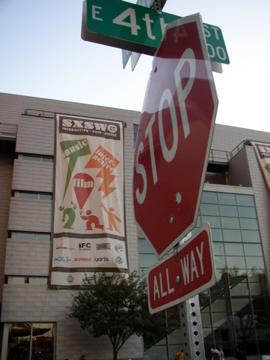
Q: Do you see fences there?
A: No, there are no fences.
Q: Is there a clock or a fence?
A: No, there are no fences or clocks.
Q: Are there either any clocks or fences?
A: No, there are no fences or clocks.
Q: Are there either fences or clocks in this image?
A: No, there are no fences or clocks.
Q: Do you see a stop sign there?
A: Yes, there is a stop sign.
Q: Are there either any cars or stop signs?
A: Yes, there is a stop sign.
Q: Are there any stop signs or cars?
A: Yes, there is a stop sign.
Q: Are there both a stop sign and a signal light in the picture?
A: No, there is a stop sign but no traffic lights.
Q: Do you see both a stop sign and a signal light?
A: No, there is a stop sign but no traffic lights.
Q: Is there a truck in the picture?
A: No, there are no trucks.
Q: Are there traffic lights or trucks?
A: No, there are no trucks or traffic lights.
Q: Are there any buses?
A: No, there are no buses.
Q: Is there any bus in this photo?
A: No, there are no buses.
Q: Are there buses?
A: No, there are no buses.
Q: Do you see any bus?
A: No, there are no buses.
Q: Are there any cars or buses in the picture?
A: No, there are no buses or cars.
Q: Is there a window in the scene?
A: Yes, there is a window.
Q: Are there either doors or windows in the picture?
A: Yes, there is a window.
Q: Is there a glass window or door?
A: Yes, there is a glass window.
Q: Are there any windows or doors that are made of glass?
A: Yes, the window is made of glass.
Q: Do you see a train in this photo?
A: No, there are no trains.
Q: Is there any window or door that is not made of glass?
A: No, there is a window but it is made of glass.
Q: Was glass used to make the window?
A: Yes, the window is made of glass.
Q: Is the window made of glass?
A: Yes, the window is made of glass.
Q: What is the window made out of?
A: The window is made of glass.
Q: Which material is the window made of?
A: The window is made of glass.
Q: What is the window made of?
A: The window is made of glass.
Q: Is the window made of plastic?
A: No, the window is made of glass.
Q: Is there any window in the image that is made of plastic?
A: No, there is a window but it is made of glass.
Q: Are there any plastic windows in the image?
A: No, there is a window but it is made of glass.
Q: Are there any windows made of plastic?
A: No, there is a window but it is made of glass.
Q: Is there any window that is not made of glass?
A: No, there is a window but it is made of glass.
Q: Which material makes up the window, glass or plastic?
A: The window is made of glass.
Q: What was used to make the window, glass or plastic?
A: The window is made of glass.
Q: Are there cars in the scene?
A: No, there are no cars.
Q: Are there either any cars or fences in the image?
A: No, there are no cars or fences.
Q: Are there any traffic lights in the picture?
A: No, there are no traffic lights.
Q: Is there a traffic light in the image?
A: No, there are no traffic lights.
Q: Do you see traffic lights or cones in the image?
A: No, there are no traffic lights or cones.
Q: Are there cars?
A: No, there are no cars.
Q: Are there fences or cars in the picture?
A: No, there are no cars or fences.